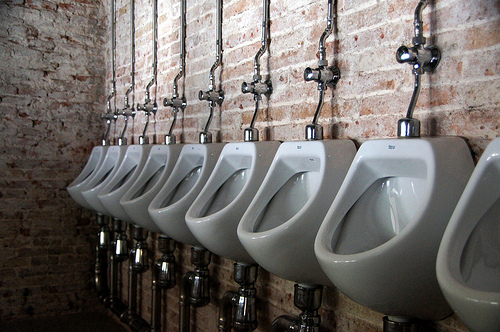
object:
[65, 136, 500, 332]
urinals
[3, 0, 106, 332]
wall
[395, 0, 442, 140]
pipe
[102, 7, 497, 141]
wall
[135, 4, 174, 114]
sunlight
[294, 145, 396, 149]
printing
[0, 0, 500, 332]
picture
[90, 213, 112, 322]
pipe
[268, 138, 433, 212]
sunlight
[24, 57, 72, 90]
crack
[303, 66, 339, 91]
handle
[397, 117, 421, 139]
to urnial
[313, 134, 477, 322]
bowl